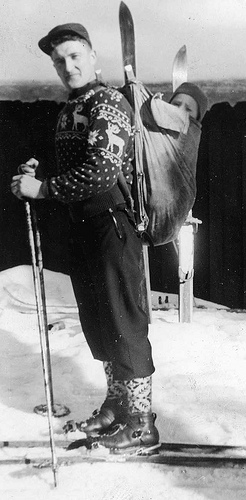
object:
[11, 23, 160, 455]
man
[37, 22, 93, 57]
hat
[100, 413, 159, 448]
shoe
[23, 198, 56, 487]
poles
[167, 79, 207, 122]
baby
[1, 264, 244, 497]
snow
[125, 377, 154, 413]
sock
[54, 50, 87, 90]
face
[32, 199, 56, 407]
ski poles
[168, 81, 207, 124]
cap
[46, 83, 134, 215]
sweater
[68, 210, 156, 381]
pants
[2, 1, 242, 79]
sky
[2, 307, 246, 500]
snow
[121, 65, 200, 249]
knapsack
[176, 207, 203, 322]
object